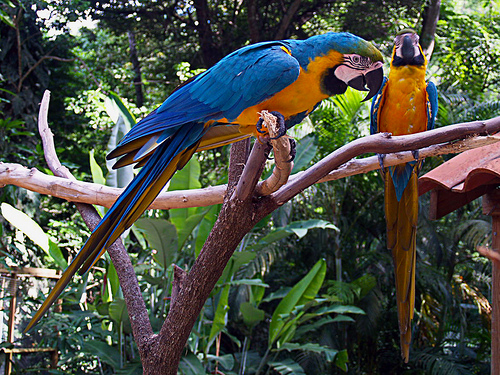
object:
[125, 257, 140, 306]
edge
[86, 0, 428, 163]
tree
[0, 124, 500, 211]
perch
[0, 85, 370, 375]
trees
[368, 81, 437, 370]
feather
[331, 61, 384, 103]
beak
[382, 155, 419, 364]
tail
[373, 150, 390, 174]
twig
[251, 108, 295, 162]
talons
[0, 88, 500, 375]
branch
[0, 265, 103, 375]
structure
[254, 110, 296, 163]
feet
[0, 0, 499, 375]
plants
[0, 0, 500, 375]
magazine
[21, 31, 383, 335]
bird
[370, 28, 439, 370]
bird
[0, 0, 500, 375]
bird perch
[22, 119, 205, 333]
tail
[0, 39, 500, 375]
foliage